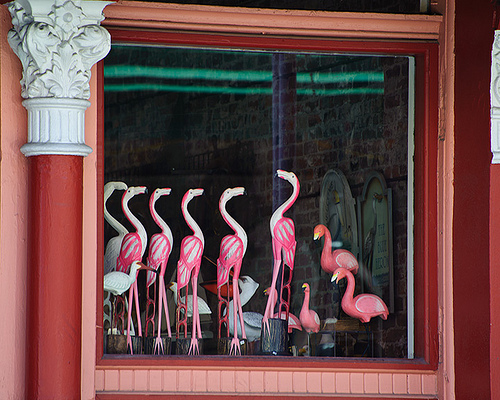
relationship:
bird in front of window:
[217, 186, 248, 357] [65, 4, 455, 384]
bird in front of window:
[115, 186, 149, 355] [97, 45, 412, 357]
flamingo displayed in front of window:
[145, 187, 173, 355] [97, 45, 412, 357]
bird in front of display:
[217, 186, 248, 357] [84, 23, 430, 363]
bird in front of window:
[261, 169, 300, 338] [97, 45, 412, 357]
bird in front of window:
[310, 220, 360, 283] [104, 27, 432, 352]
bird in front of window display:
[332, 267, 403, 369] [99, 53, 424, 363]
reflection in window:
[103, 59, 386, 99] [97, 45, 412, 357]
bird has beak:
[314, 224, 360, 320] [307, 227, 322, 243]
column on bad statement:
[3, 2, 125, 397] [0, 0, 500, 400]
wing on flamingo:
[272, 217, 303, 264] [262, 153, 302, 336]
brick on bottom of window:
[91, 366, 447, 398] [97, 45, 412, 357]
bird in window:
[331, 267, 389, 358] [97, 45, 412, 357]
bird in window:
[314, 224, 360, 320] [97, 45, 412, 357]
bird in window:
[261, 169, 300, 338] [65, 4, 455, 384]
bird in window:
[331, 267, 389, 358] [65, 4, 455, 384]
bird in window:
[217, 186, 248, 357] [65, 4, 455, 384]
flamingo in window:
[135, 182, 176, 344] [65, 4, 455, 384]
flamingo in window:
[177, 188, 205, 356] [65, 4, 455, 384]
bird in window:
[217, 186, 248, 357] [104, 27, 432, 352]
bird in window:
[331, 267, 389, 358] [104, 27, 432, 352]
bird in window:
[314, 224, 360, 320] [104, 27, 432, 352]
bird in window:
[299, 283, 320, 356] [104, 27, 432, 352]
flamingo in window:
[175, 186, 201, 355] [104, 27, 432, 352]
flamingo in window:
[177, 188, 205, 356] [97, 45, 412, 357]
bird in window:
[115, 186, 149, 355] [104, 27, 432, 352]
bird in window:
[265, 165, 300, 333] [93, 41, 436, 371]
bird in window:
[213, 181, 252, 355] [93, 41, 436, 371]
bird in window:
[331, 267, 389, 358] [93, 41, 436, 371]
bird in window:
[298, 278, 319, 355] [93, 41, 436, 371]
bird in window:
[118, 184, 143, 353] [93, 41, 436, 371]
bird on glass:
[115, 186, 149, 355] [104, 57, 406, 355]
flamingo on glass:
[145, 187, 173, 355] [104, 57, 406, 355]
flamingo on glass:
[177, 188, 205, 356] [104, 57, 406, 355]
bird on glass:
[217, 186, 248, 357] [104, 57, 406, 355]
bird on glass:
[261, 169, 300, 338] [104, 57, 406, 355]